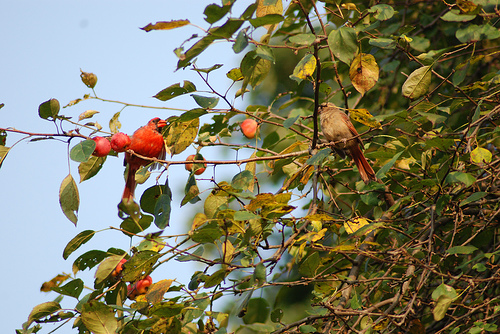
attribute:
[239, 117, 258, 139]
apple — hanging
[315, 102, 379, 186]
bird — perched, brown, in tree, yellow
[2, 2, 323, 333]
sky — blue, in background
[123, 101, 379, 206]
birds — together, perched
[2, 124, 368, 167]
branch — brown, brown with leaves, leafy, brown with fruit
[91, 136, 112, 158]
apple — on tree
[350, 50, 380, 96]
leaf — browned, hanging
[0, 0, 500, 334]
photo — autumn, daytime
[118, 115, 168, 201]
bird — red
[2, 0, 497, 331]
leaves — green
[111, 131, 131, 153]
fruit — red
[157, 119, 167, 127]
beak — red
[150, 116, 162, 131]
face — black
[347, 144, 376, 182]
tail — brown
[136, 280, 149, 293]
berry — red